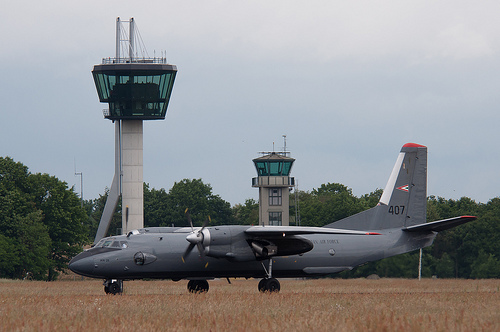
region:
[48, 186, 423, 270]
plane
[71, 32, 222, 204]
traffic controller tower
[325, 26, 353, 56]
white clouds in blue sky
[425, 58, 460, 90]
white clouds in blue sky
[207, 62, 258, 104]
white clouds in blue sky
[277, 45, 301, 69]
white clouds in blue sky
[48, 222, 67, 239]
Green leaves on a tree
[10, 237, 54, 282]
Green leaves on a tree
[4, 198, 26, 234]
Green leaves on a tree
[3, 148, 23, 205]
Green leaves on a tree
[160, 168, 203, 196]
Green leaves on a tree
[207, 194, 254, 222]
Green leaves on a tree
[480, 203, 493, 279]
Green leaves on a tree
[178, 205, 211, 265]
Propellers on an aircraft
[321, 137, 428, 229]
Vertical stabilizer on an aircraft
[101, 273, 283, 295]
Landing gear of an aircraft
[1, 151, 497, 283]
Trees surrounding the grassy field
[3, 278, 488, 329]
Brown grass in a field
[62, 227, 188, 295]
Front end of an aircraft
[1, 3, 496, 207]
Gray, dreary sky overhead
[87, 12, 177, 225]
A tower in a field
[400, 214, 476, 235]
Rear wing on an aircraft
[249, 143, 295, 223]
Tower in a field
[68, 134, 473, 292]
the jet is gray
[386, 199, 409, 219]
black numbers on plane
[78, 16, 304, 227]
plane towers in background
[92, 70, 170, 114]
tower windows are green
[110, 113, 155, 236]
tower structure is white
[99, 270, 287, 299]
plane wheels touching the ground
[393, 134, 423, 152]
tip of tail is red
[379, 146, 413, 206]
plane tail is white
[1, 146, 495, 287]
trees behind the towers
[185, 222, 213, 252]
propeller nose is silver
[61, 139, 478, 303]
gray airplane sitting on runway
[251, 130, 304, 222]
tower for air traffic controllers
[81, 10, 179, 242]
tower in field next to runway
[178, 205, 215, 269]
propeller on gray airplane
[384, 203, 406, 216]
number identifying airplane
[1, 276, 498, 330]
brown grass in field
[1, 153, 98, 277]
green trees along side of field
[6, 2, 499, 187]
slightly overcast sky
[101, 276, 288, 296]
three sets of wheels on airplane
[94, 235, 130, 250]
windows in front of airplane